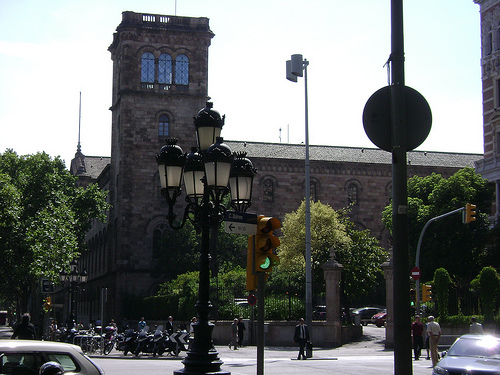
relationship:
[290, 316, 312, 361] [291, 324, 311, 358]
man wears suit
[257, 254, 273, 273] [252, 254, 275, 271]
light on light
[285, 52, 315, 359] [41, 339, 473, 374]
light pole on street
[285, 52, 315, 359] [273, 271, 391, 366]
light pole on a corner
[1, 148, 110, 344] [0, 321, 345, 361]
tree on sidewalk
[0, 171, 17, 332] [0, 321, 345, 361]
tree on sidewalk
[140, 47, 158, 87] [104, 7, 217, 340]
window in a building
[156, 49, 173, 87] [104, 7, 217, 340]
window in a building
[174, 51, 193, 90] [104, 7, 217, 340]
window in a building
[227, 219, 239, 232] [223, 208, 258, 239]
arrow on street sign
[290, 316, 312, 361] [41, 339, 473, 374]
man crossing street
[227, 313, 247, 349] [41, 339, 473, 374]
couple crossing street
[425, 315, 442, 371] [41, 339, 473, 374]
man crossing street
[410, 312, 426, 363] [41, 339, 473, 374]
man crossing street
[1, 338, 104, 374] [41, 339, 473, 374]
car on street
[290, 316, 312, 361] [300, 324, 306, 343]
man wears tie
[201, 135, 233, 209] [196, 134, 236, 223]
light has metal case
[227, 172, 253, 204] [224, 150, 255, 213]
light has metal case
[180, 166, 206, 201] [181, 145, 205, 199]
light has metal case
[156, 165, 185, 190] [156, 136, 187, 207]
light has metal case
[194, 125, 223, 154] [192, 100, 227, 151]
light has metal case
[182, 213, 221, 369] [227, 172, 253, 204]
light post has light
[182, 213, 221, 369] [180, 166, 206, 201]
light post has light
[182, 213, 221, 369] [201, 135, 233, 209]
light post has light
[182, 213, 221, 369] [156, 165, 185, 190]
light post has light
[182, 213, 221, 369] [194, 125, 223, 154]
light post has light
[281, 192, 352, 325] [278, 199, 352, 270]
tree has leaves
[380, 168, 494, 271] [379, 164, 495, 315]
leaves on tree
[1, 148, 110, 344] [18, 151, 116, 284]
tree has leaves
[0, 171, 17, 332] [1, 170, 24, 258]
tree has leaves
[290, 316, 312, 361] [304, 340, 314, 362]
man carries suitcase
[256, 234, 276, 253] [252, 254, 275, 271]
light on light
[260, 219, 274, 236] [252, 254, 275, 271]
light on light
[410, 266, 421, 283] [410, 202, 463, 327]
road sign on a pole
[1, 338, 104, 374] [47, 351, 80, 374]
car has back window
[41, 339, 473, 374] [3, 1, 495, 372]
street in a town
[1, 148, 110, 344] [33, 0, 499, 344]
tree beside building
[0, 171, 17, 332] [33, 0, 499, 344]
tree beside building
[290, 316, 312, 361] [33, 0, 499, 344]
man near to building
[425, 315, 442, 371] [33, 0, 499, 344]
man near to building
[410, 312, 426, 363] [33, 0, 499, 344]
man near to building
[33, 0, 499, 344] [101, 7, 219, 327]
building has tower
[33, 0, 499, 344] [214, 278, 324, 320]
building has fence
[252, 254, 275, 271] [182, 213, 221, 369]
light next to light post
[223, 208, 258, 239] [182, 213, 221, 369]
street sign next to light post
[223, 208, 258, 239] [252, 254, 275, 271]
street sign next to light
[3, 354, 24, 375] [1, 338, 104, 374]
passenger in car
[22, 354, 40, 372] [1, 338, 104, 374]
passenger in car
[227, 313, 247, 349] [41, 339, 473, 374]
couple are crossing street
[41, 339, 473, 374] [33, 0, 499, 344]
street alongside building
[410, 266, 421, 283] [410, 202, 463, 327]
road sign on pole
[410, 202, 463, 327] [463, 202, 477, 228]
pole has stoplight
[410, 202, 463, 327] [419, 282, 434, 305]
pole has stoplight